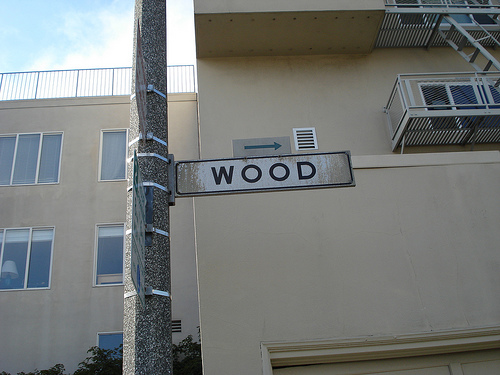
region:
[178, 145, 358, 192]
The sign is black and white.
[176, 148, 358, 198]
The sign is in English.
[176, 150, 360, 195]
The word on the sign is in black.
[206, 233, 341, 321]
The building is beige.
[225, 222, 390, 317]
The building is smooth.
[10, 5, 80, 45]
The sky is blue.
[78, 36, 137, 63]
The cloud is white.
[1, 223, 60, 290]
The window frame is white.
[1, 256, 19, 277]
The lamp shade is white.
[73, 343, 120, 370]
The tree leaves are green.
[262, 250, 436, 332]
A white house wall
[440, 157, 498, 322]
A white house wall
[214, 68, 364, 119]
A white house wall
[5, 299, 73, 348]
A white house wall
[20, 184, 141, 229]
A white house wall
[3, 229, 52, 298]
A clear glass window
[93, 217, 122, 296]
A clear glass window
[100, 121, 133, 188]
A clear glass window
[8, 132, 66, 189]
A clear glass window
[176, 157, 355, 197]
A sign with the word wood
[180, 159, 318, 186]
street sign for wood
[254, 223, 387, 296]
the building is tan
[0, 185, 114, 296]
windows on the building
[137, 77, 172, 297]
rungs on the pole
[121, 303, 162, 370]
the pole is metal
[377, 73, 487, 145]
railing on the building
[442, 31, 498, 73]
ladder on the building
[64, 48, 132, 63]
the clouds are large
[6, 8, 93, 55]
part of the sky is blue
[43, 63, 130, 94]
railing on the roof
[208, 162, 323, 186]
the word wood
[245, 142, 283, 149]
an arrow pointing to the right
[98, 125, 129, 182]
the window of a building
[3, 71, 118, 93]
metal bars on the top of a building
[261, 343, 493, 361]
a door frame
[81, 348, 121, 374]
plants near the wall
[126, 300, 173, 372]
a concrete mast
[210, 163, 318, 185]
letters written in black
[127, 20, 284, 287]
3 sign posts on a pole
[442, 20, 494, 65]
a metal ladder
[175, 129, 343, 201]
street sign for wood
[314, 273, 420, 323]
the building is tan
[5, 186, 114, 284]
windows for the building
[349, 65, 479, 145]
fire escape on building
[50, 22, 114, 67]
clouds in the sky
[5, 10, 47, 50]
blue in the sky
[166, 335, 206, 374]
top of the tree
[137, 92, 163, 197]
rungs on the pole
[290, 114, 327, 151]
vent of the buildign